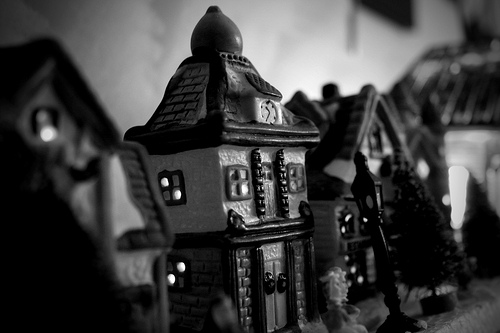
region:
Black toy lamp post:
[351, 157, 417, 302]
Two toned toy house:
[155, 32, 311, 306]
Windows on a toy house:
[215, 162, 260, 193]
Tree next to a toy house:
[388, 151, 463, 309]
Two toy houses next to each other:
[209, 70, 421, 273]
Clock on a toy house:
[249, 84, 284, 123]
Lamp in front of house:
[353, 155, 410, 318]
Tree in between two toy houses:
[440, 146, 492, 249]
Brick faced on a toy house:
[188, 255, 228, 310]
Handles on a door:
[270, 265, 288, 288]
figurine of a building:
[134, 7, 356, 331]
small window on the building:
[216, 157, 256, 198]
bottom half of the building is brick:
[175, 248, 320, 331]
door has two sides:
[259, 258, 302, 328]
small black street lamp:
[341, 146, 428, 331]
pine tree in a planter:
[383, 158, 474, 321]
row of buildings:
[8, 16, 466, 331]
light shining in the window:
[173, 189, 181, 198]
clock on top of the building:
[256, 101, 285, 122]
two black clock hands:
[264, 102, 271, 122]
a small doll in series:
[170, 20, 317, 329]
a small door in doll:
[252, 150, 300, 228]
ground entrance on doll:
[252, 249, 298, 330]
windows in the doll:
[156, 170, 187, 212]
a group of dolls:
[31, 82, 497, 315]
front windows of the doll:
[228, 160, 246, 202]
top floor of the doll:
[148, 129, 315, 230]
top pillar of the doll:
[176, 5, 268, 65]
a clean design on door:
[262, 254, 299, 329]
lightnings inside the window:
[156, 172, 194, 206]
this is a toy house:
[175, 15, 294, 326]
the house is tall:
[186, 60, 301, 317]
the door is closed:
[252, 241, 287, 328]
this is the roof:
[173, 61, 239, 118]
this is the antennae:
[190, 1, 239, 56]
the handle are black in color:
[265, 276, 287, 291]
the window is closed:
[160, 171, 183, 202]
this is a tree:
[406, 197, 443, 270]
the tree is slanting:
[392, 195, 441, 268]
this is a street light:
[348, 158, 383, 224]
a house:
[134, 114, 294, 323]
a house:
[76, 24, 304, 316]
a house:
[211, 146, 328, 323]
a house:
[201, 92, 286, 294]